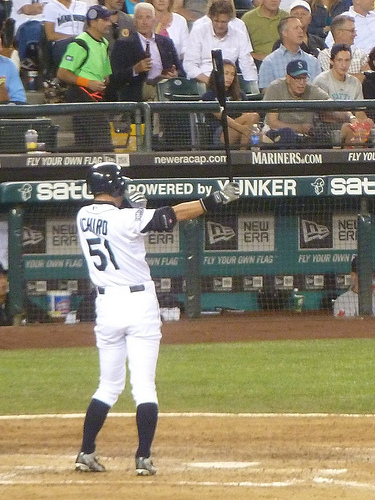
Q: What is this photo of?
A: A field.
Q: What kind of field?
A: A baseball field.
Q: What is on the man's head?
A: A helmet.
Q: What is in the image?
A: Baseball.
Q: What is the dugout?
A: Baseball.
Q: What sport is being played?
A: Baseball.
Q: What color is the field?
A: Brown, green, and white.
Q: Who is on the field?
A: The baseball player.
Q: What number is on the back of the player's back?
A: 51.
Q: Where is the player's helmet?
A: On his head.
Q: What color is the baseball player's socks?
A: Black.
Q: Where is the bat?
A: In the player's hand.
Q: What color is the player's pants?
A: White.